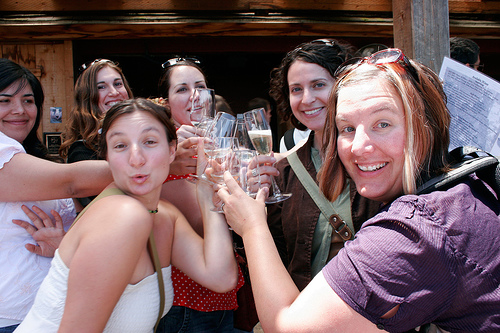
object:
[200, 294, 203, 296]
polka dots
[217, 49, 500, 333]
girls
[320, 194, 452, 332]
sleeve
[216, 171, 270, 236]
hand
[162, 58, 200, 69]
sunglasses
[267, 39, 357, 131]
hair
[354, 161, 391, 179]
smile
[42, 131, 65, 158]
placque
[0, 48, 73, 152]
wall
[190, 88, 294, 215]
toasted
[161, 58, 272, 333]
woman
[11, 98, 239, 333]
woman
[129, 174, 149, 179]
kiss lips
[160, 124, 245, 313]
shirt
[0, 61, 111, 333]
female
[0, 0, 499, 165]
restaurant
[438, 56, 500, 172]
menu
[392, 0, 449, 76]
beam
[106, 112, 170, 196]
kissing face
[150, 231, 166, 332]
purse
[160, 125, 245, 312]
dress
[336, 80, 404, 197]
face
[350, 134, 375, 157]
nose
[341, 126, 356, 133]
eye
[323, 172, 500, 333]
shirt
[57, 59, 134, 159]
hair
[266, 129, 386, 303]
jacket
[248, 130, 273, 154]
champagne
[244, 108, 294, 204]
glass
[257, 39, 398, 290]
person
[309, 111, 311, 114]
teeth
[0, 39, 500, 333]
party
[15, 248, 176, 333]
top